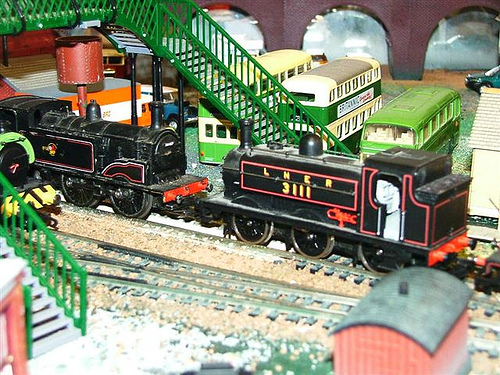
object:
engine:
[200, 118, 472, 274]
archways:
[420, 7, 500, 80]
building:
[466, 88, 500, 221]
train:
[0, 95, 500, 295]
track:
[22, 238, 500, 357]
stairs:
[253, 125, 279, 136]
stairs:
[32, 305, 63, 328]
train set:
[2, 1, 499, 373]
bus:
[197, 48, 312, 167]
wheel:
[288, 208, 337, 262]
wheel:
[107, 176, 152, 217]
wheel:
[59, 168, 104, 210]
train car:
[200, 117, 472, 254]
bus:
[360, 85, 460, 163]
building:
[326, 266, 474, 373]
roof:
[326, 264, 473, 355]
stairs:
[261, 132, 287, 145]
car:
[463, 65, 500, 98]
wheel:
[356, 238, 396, 273]